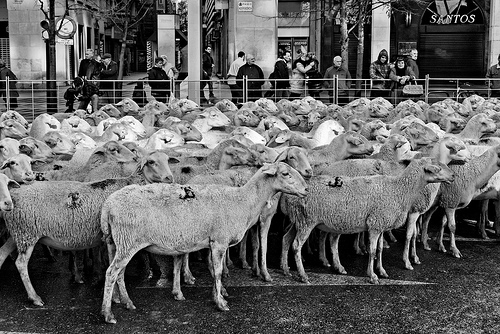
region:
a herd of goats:
[0, 91, 499, 317]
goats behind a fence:
[0, 77, 496, 330]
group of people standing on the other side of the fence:
[66, 38, 439, 103]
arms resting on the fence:
[386, 66, 421, 90]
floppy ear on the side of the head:
[262, 164, 279, 181]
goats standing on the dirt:
[3, 98, 497, 326]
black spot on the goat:
[86, 175, 133, 192]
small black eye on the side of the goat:
[282, 168, 290, 181]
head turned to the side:
[4, 153, 46, 185]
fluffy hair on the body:
[10, 180, 110, 251]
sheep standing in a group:
[86, 161, 313, 328]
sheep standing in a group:
[7, 145, 184, 316]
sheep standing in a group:
[275, 157, 462, 289]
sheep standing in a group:
[35, 136, 144, 196]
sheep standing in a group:
[192, 103, 236, 135]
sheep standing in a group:
[157, 116, 205, 145]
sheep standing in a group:
[390, 117, 446, 152]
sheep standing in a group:
[372, 93, 399, 113]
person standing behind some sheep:
[145, 52, 175, 99]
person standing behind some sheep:
[370, 47, 392, 84]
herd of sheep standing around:
[5, 90, 498, 310]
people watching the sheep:
[68, 44, 416, 101]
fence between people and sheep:
[2, 79, 499, 114]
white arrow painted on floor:
[135, 241, 431, 306]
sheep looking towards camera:
[1, 152, 176, 279]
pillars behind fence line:
[178, 4, 393, 89]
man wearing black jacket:
[234, 52, 263, 95]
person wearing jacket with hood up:
[365, 47, 391, 87]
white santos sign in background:
[426, 7, 481, 27]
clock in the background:
[52, 10, 79, 42]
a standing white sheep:
[104, 155, 307, 320]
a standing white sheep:
[4, 150, 172, 311]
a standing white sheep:
[282, 154, 452, 278]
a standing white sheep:
[413, 140, 497, 258]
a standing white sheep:
[299, 129, 370, 168]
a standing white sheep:
[2, 152, 37, 184]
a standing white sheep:
[4, 133, 56, 162]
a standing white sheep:
[55, 127, 93, 152]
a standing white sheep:
[189, 103, 230, 133]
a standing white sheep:
[297, 116, 347, 144]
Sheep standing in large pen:
[52, 99, 431, 295]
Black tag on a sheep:
[165, 186, 203, 206]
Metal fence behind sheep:
[53, 74, 257, 114]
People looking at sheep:
[222, 41, 343, 81]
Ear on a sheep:
[259, 162, 283, 184]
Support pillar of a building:
[179, 45, 209, 107]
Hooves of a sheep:
[210, 286, 237, 320]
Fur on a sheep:
[320, 186, 380, 229]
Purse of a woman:
[399, 74, 426, 96]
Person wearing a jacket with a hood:
[367, 46, 397, 103]